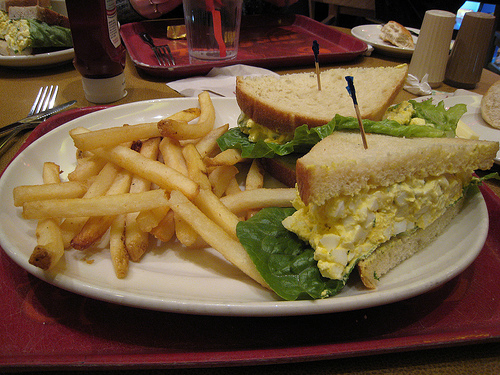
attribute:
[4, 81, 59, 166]
fork — Silver 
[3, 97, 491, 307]
dish — white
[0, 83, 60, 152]
knife — Silver 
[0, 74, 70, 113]
fork — silver 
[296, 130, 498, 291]
sandwich — Egg salad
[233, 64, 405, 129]
sandwich — Egg salad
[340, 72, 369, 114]
toothpick — blue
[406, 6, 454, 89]
salt shaker — Salt 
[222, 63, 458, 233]
sandwich — triangle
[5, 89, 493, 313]
plate — white 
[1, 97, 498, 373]
tray — red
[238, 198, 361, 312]
leaf — green, spainch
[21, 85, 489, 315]
dish — White 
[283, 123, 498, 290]
sandwich — triangle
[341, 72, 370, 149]
toothpick — sticking 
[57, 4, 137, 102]
bottle — Plastic , ketchup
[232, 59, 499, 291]
sandwich — Egg salad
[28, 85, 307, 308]
fries — piled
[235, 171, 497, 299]
leaf — green